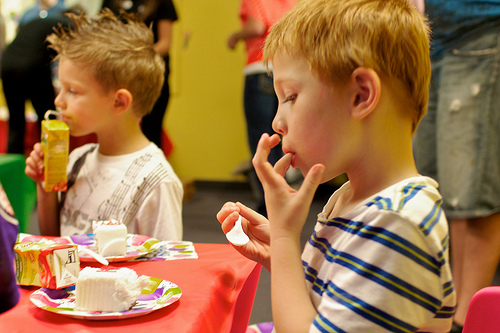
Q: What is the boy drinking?
A: Juice.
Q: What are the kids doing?
A: Eating.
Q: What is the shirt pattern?
A: Stripe.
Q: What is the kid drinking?
A: Juice.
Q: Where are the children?
A: At a party.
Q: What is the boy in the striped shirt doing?
A: Licking his fingers.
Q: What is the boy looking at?
A: A piece of cake on a plate.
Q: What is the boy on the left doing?
A: Drinking a beverage.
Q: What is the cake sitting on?
A: A paper plate.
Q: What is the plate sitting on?
A: A table with a red tablecloth.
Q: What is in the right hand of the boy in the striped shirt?
A: A plastic spoon.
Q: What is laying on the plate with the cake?
A: A juice box.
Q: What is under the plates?
A: A table with a red tablecloth.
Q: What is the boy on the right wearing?
A: A blue and white striped shirt.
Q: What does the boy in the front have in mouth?
A: Fingers.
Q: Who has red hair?
A: Boy in front.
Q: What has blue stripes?
A: Red hair boys shirt.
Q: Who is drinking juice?
A: Boy with mohawk.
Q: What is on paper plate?
A: Cake.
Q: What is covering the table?
A: Orange table cloth.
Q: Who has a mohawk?
A: Boy drinking juice.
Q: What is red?
A: Cloth.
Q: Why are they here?
A: To eat.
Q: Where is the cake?
A: On the plate.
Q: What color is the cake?
A: White.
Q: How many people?
A: 6.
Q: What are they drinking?
A: Juice.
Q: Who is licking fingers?
A: A boy.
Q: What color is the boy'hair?
A: Blonde.